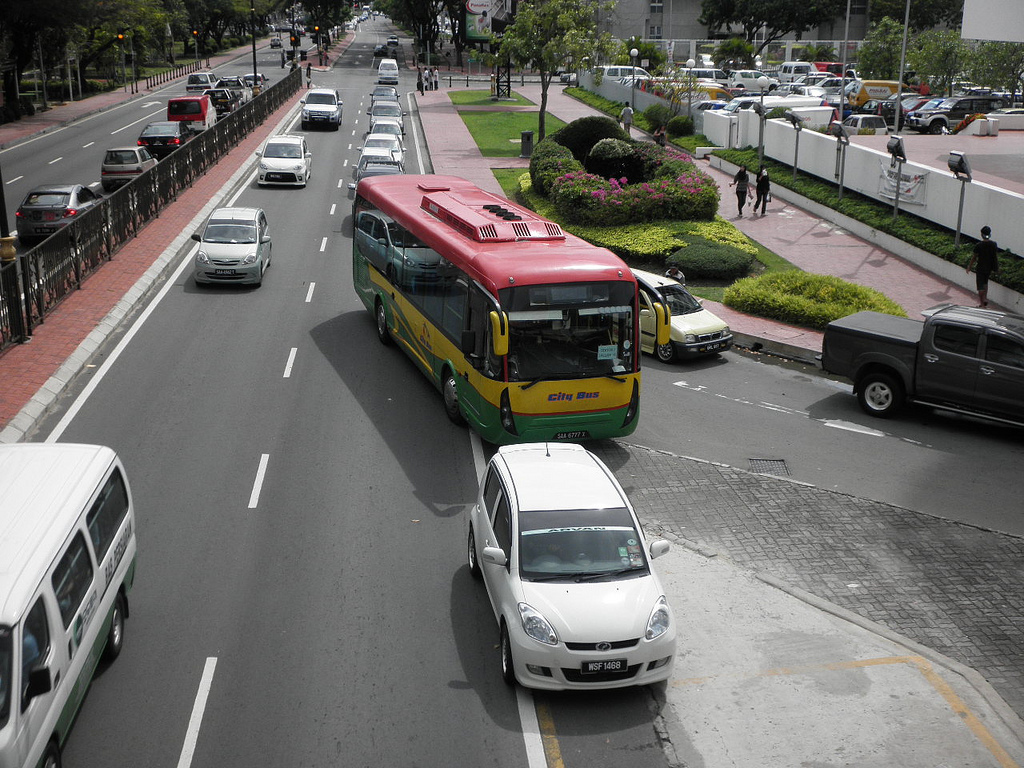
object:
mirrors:
[654, 233, 679, 267]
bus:
[469, 130, 855, 334]